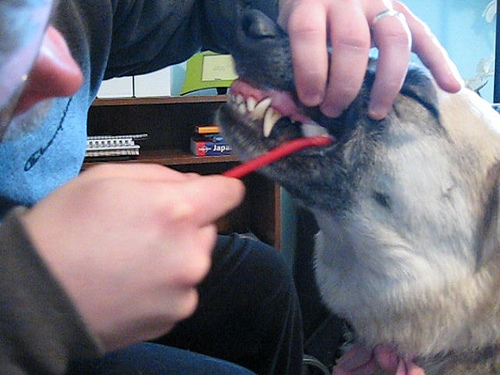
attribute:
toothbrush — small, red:
[297, 122, 334, 159]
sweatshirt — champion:
[0, 1, 275, 371]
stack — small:
[189, 124, 234, 154]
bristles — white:
[301, 123, 327, 138]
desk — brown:
[77, 86, 292, 245]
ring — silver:
[368, 9, 406, 39]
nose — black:
[237, 6, 282, 41]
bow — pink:
[329, 338, 431, 373]